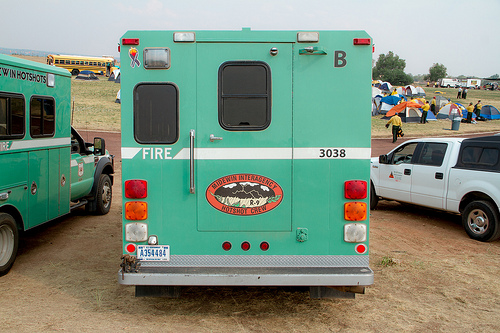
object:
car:
[369, 133, 500, 241]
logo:
[205, 173, 284, 216]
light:
[344, 223, 367, 243]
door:
[195, 44, 293, 233]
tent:
[478, 104, 499, 120]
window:
[135, 82, 177, 144]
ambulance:
[116, 27, 373, 296]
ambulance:
[0, 55, 114, 277]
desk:
[434, 98, 464, 114]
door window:
[218, 60, 271, 129]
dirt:
[2, 129, 496, 331]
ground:
[1, 71, 498, 331]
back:
[119, 29, 370, 287]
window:
[214, 60, 272, 130]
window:
[27, 93, 55, 138]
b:
[334, 50, 347, 68]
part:
[244, 27, 373, 295]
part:
[354, 223, 367, 242]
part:
[241, 60, 271, 132]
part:
[154, 80, 182, 146]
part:
[44, 93, 56, 138]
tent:
[435, 103, 470, 120]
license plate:
[137, 245, 170, 261]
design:
[206, 173, 284, 216]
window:
[386, 142, 418, 164]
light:
[345, 180, 367, 199]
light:
[344, 202, 367, 220]